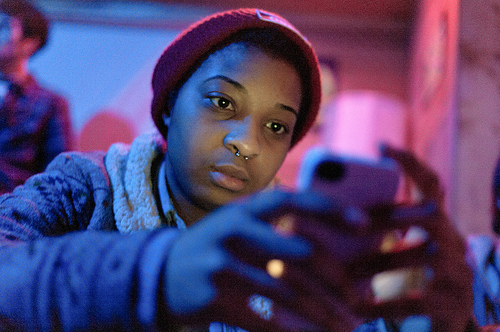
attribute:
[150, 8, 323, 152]
hat — red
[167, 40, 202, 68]
fabric — red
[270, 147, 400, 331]
phone — white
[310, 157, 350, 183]
lens — black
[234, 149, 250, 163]
ring — pierced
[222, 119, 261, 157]
nose — pierced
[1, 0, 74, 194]
man — standing, in the background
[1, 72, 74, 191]
shirt — plaid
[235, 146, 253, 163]
septum — pierced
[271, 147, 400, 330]
phone case — white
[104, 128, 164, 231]
scarf — white